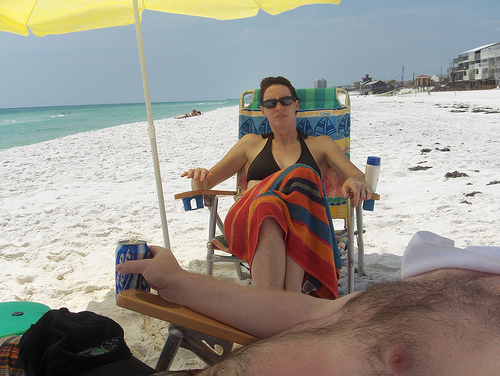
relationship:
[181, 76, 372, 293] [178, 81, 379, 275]
lady in beach chair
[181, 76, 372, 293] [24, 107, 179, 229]
lady at beach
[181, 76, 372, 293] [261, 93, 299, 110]
lady wearing glasses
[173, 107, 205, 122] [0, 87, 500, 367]
people lying on beach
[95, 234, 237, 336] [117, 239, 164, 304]
hand holding beer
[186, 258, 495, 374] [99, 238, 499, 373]
chest of man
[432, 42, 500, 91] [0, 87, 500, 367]
beach house beside beach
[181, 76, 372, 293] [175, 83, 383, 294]
lady sitting in beach chair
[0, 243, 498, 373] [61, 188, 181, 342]
man holding can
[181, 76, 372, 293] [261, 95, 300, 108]
lady wearing sunglasses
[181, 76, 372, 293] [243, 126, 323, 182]
lady wearing top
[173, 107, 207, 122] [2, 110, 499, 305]
people lying on beach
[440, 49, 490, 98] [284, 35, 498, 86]
beach house in background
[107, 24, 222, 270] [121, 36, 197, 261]
pole on umbrella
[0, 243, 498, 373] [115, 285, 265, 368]
man laying in chair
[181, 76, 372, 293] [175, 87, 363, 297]
lady sitting in chair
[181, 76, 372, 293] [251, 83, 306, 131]
lady wearing glasses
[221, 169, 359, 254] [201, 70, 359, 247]
towel on lap of lady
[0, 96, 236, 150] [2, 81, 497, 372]
water in front of sand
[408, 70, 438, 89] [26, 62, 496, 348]
building behind beach